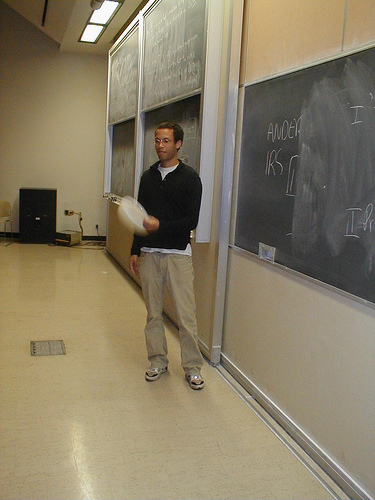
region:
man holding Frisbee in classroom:
[114, 115, 207, 393]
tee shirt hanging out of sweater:
[134, 242, 195, 257]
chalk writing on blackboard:
[256, 105, 310, 182]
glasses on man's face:
[150, 134, 180, 150]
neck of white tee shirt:
[153, 163, 178, 179]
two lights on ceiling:
[76, 4, 125, 51]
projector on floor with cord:
[53, 206, 102, 251]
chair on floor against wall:
[0, 195, 15, 250]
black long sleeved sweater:
[125, 161, 203, 260]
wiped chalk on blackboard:
[308, 142, 359, 191]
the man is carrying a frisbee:
[102, 172, 212, 303]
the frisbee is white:
[117, 188, 152, 239]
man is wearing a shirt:
[112, 158, 196, 243]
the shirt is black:
[95, 150, 262, 263]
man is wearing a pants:
[120, 244, 213, 364]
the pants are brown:
[127, 252, 232, 398]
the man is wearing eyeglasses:
[139, 125, 190, 159]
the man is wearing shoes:
[132, 355, 218, 405]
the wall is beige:
[30, 99, 105, 163]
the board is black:
[249, 185, 291, 235]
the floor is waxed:
[76, 402, 174, 491]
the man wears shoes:
[136, 342, 212, 404]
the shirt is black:
[135, 152, 201, 253]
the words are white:
[249, 90, 324, 203]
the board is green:
[246, 107, 295, 202]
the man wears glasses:
[143, 118, 191, 173]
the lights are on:
[72, 1, 133, 58]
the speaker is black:
[14, 175, 74, 268]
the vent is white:
[20, 327, 85, 374]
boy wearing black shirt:
[126, 122, 229, 388]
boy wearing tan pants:
[124, 122, 229, 389]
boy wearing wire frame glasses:
[124, 120, 218, 387]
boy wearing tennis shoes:
[125, 121, 220, 391]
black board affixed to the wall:
[229, 43, 373, 310]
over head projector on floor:
[54, 208, 83, 243]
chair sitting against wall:
[0, 201, 15, 244]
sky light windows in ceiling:
[77, 0, 124, 44]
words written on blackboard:
[251, 105, 374, 241]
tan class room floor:
[2, 236, 338, 499]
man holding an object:
[111, 116, 217, 392]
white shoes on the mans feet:
[137, 359, 217, 395]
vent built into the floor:
[15, 332, 79, 366]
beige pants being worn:
[121, 245, 207, 374]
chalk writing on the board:
[263, 105, 306, 200]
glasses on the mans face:
[150, 137, 183, 147]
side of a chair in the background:
[1, 188, 12, 252]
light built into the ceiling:
[66, 2, 135, 51]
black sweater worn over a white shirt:
[134, 163, 199, 252]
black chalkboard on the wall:
[229, 77, 369, 313]